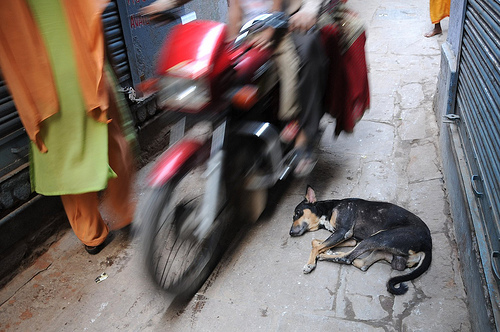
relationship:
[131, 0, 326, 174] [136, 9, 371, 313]
man on motorcycle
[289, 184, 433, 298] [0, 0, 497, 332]
dog on ground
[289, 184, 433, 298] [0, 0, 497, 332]
dog on street